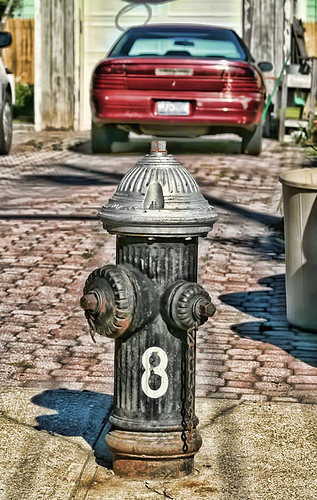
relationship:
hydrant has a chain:
[80, 141, 219, 480] [187, 326, 197, 446]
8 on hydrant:
[140, 347, 169, 398] [80, 141, 219, 480]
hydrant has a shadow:
[80, 141, 219, 480] [29, 387, 114, 468]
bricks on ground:
[1, 131, 316, 407] [1, 130, 316, 404]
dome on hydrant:
[97, 140, 218, 241] [80, 141, 219, 480]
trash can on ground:
[277, 167, 316, 334] [1, 130, 316, 404]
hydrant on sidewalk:
[80, 141, 219, 480] [0, 386, 316, 500]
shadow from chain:
[179, 338, 188, 454] [187, 326, 197, 446]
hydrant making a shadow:
[80, 141, 219, 480] [29, 387, 114, 468]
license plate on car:
[156, 101, 190, 117] [90, 22, 271, 157]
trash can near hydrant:
[277, 167, 316, 334] [80, 141, 219, 480]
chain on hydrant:
[187, 326, 197, 446] [80, 141, 219, 480]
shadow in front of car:
[114, 0, 174, 34] [90, 22, 271, 157]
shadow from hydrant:
[29, 387, 114, 468] [80, 141, 219, 480]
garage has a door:
[32, 0, 291, 133] [80, 1, 243, 142]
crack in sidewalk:
[0, 399, 252, 499] [0, 386, 316, 500]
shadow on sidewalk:
[29, 387, 114, 468] [0, 386, 316, 500]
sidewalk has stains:
[0, 386, 316, 500] [0, 393, 316, 499]